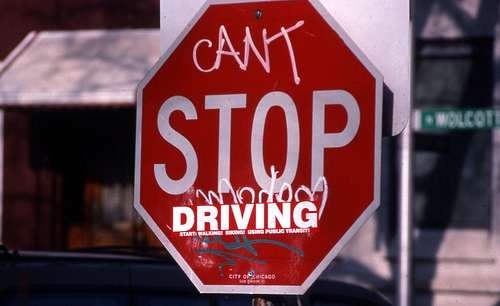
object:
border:
[199, 281, 310, 294]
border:
[370, 73, 384, 202]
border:
[131, 82, 144, 208]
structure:
[412, 224, 484, 303]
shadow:
[421, 27, 484, 224]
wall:
[417, 213, 485, 297]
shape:
[128, 4, 386, 292]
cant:
[191, 20, 306, 84]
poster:
[128, 2, 387, 296]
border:
[300, 202, 381, 290]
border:
[132, 205, 202, 289]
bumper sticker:
[167, 202, 323, 233]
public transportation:
[180, 227, 313, 236]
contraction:
[188, 20, 308, 82]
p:
[309, 87, 360, 192]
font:
[152, 89, 364, 201]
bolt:
[254, 10, 263, 19]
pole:
[254, 295, 272, 304]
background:
[422, 109, 499, 131]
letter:
[474, 112, 486, 126]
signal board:
[134, 2, 384, 292]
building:
[2, 29, 164, 251]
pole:
[396, 20, 412, 303]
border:
[205, 0, 274, 6]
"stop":
[153, 90, 361, 194]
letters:
[154, 95, 199, 195]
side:
[137, 0, 207, 90]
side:
[304, 1, 386, 81]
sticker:
[174, 203, 323, 232]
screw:
[247, 269, 256, 277]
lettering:
[425, 110, 476, 129]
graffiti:
[150, 14, 360, 280]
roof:
[2, 25, 160, 106]